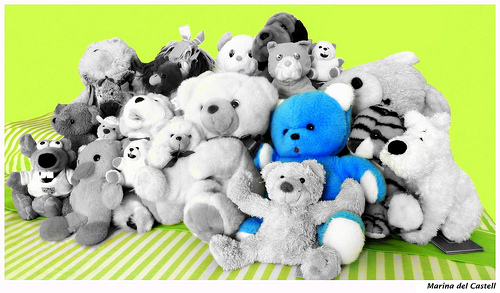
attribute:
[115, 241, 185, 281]
stripes — white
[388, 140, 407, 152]
dog nose — black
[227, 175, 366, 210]
hands — out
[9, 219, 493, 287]
stripes — green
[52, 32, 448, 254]
animals — stuffed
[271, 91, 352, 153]
bear — teddy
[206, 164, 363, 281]
bear — small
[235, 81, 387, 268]
bear — larger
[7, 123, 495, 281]
stripes — white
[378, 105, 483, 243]
dog — stuffed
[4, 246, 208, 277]
ground — striped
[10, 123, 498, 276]
ground — green